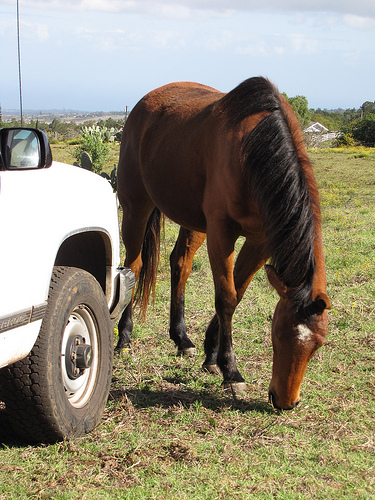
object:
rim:
[62, 302, 99, 410]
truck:
[0, 127, 138, 444]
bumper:
[111, 262, 135, 326]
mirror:
[2, 125, 52, 168]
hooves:
[225, 378, 244, 394]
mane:
[243, 102, 319, 314]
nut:
[70, 351, 79, 361]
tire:
[6, 267, 115, 444]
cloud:
[0, 0, 375, 64]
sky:
[0, 0, 375, 118]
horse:
[115, 73, 332, 413]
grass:
[343, 151, 375, 272]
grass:
[249, 412, 350, 482]